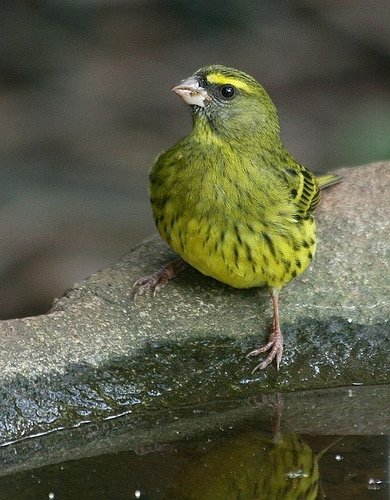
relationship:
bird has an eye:
[132, 64, 345, 374] [217, 84, 235, 100]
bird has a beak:
[132, 64, 345, 374] [170, 73, 206, 111]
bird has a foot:
[132, 64, 345, 374] [247, 328, 287, 374]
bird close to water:
[132, 64, 345, 374] [0, 384, 389, 497]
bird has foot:
[132, 64, 345, 374] [247, 328, 287, 374]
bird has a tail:
[132, 64, 345, 374] [310, 163, 350, 194]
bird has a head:
[132, 64, 345, 374] [169, 60, 280, 143]